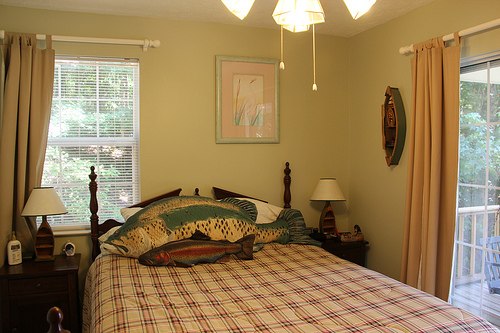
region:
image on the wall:
[211, 46, 301, 134]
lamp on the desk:
[23, 180, 73, 266]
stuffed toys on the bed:
[113, 188, 319, 268]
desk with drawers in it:
[3, 232, 80, 327]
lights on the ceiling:
[209, 3, 394, 89]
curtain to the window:
[400, 33, 465, 288]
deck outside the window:
[452, 193, 499, 310]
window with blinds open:
[41, 52, 146, 229]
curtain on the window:
[3, 40, 49, 252]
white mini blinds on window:
[52, 56, 152, 208]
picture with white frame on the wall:
[207, 48, 288, 160]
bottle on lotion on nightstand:
[5, 230, 27, 267]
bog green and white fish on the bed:
[101, 190, 312, 246]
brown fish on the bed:
[135, 228, 263, 269]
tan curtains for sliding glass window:
[407, 28, 462, 302]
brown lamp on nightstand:
[20, 183, 61, 270]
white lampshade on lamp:
[19, 178, 73, 269]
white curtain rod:
[1, 25, 169, 50]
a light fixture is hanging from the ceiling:
[217, 0, 383, 100]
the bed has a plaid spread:
[88, 243, 494, 332]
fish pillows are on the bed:
[103, 190, 304, 271]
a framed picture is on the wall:
[213, 52, 281, 147]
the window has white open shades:
[33, 54, 140, 232]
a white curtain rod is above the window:
[5, 30, 170, 240]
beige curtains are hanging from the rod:
[10, 30, 64, 270]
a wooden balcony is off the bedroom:
[448, 188, 499, 312]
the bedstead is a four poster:
[53, 154, 485, 331]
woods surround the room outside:
[45, 60, 499, 276]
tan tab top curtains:
[401, 25, 460, 300]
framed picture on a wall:
[190, 31, 295, 166]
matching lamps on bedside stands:
[7, 155, 372, 288]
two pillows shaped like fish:
[98, 182, 319, 273]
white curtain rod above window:
[0, 25, 167, 102]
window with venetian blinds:
[19, 40, 146, 238]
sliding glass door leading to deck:
[402, 26, 498, 319]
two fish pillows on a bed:
[80, 155, 337, 312]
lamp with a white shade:
[308, 169, 347, 246]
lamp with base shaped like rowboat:
[20, 178, 67, 265]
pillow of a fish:
[130, 229, 263, 280]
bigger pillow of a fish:
[91, 196, 308, 261]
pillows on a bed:
[91, 192, 318, 297]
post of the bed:
[281, 153, 296, 208]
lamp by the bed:
[311, 160, 352, 247]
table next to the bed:
[8, 243, 84, 327]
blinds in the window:
[37, 51, 146, 233]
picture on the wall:
[196, 51, 293, 167]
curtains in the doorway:
[379, 28, 471, 295]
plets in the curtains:
[396, 40, 449, 310]